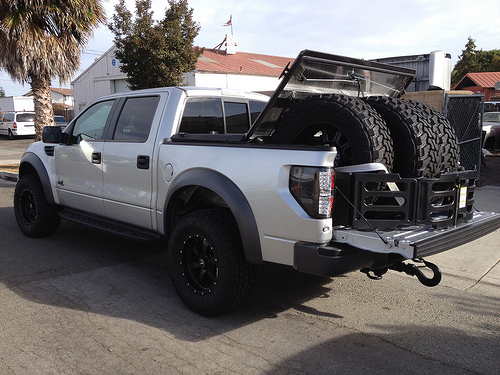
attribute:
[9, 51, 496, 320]
truck — silver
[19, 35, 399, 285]
truck — silver, open, four door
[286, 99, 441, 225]
tire — rear, black, big, three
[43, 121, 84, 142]
mirror — rear, side view, side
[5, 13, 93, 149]
tree — palm, green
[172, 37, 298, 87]
roof — red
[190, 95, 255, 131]
window — black, side, tinted, car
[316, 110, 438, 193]
wheel — large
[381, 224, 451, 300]
hook — towing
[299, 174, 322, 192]
light — rear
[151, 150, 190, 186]
cap — gas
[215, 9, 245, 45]
flag — flying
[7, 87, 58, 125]
van — white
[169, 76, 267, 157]
glass — raised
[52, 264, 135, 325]
surface — paved